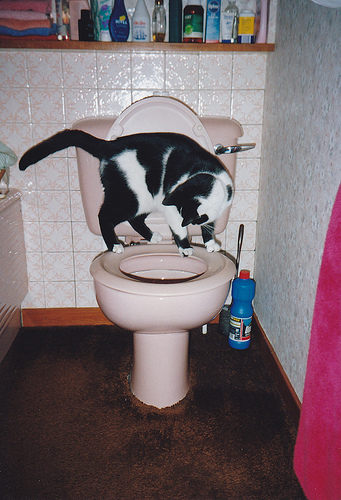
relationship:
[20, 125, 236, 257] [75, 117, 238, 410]
cat standing on toilet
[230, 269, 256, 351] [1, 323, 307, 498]
bottle on floor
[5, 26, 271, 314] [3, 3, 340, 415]
tiles on wall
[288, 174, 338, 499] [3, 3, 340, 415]
towel hanging on wall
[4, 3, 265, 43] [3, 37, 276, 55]
stuff on top of shelf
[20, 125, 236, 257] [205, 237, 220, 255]
cat has a white paw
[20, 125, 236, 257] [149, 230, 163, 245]
cat has a white paw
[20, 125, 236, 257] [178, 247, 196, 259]
cat has a white paw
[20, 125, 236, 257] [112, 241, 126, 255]
cat has a white paw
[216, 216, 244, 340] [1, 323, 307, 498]
toilet brush on floor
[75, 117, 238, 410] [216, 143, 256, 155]
toilet has a handle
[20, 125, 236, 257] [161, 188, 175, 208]
cat has a right ear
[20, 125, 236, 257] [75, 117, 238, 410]
cat on toilet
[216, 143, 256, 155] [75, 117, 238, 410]
handle on toilet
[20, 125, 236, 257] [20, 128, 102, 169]
cat has a tail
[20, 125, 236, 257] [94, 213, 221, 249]
cat has four legs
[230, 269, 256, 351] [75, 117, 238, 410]
bottle next to toilet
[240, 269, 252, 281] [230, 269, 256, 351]
cap on top of bottle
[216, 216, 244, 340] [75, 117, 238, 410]
toilet brush next to toilet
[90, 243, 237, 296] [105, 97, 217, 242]
toilet seat has a cover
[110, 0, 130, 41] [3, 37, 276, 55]
bottle on shelf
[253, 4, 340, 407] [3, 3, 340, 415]
wallpaper on wall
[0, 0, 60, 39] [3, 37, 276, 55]
towels on top of shelf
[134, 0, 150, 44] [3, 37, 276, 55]
bottle on shelf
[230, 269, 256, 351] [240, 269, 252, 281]
bottle has a cap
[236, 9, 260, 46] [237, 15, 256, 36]
powder bottle has label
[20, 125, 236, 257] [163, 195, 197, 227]
cat has ears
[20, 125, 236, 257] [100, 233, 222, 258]
cat has paws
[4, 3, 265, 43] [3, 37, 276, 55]
stuff on shelf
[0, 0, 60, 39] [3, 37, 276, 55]
towels on shelf